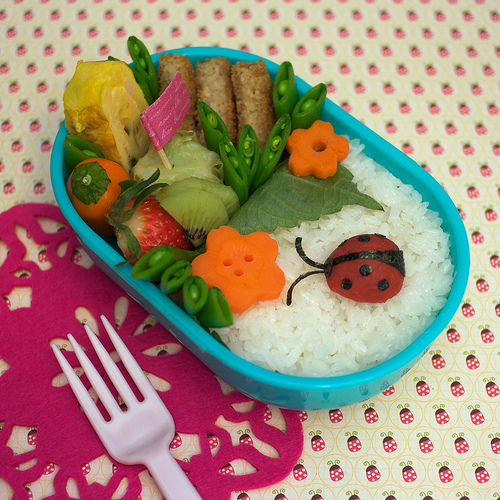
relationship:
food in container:
[94, 76, 410, 330] [58, 49, 463, 384]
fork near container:
[37, 316, 221, 497] [58, 49, 463, 384]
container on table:
[58, 49, 463, 384] [1, 3, 499, 500]